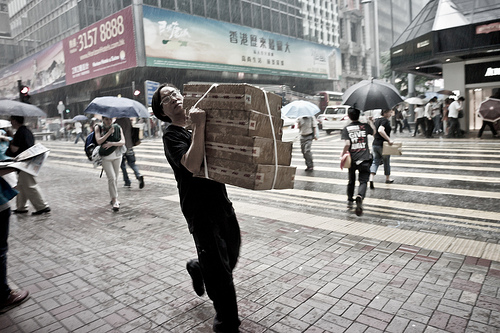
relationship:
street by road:
[2, 94, 497, 331] [29, 126, 498, 247]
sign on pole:
[16, 73, 103, 144] [49, 94, 94, 145]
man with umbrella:
[296, 120, 322, 172] [278, 97, 316, 117]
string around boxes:
[191, 78, 279, 191] [380, 143, 402, 157]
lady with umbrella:
[92, 115, 127, 212] [82, 91, 154, 123]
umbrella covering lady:
[82, 89, 158, 126] [92, 115, 127, 211]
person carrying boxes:
[149, 78, 299, 331] [181, 77, 297, 193]